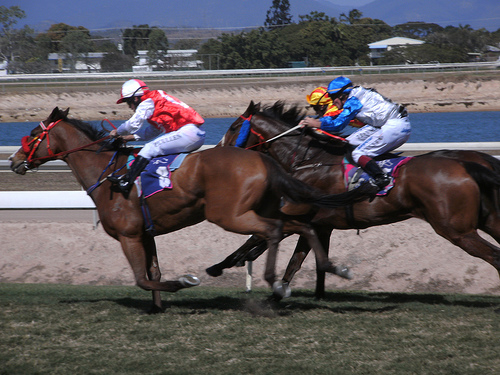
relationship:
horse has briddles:
[7, 103, 357, 320] [19, 112, 131, 173]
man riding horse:
[7, 71, 355, 318] [7, 103, 357, 320]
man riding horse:
[298, 76, 413, 192] [203, 97, 498, 294]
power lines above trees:
[11, 16, 498, 50] [13, 38, 497, 67]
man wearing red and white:
[7, 71, 355, 318] [108, 89, 208, 195]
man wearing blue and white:
[298, 76, 413, 192] [314, 72, 415, 196]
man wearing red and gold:
[205, 79, 500, 312] [308, 83, 367, 134]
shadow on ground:
[56, 290, 253, 326] [6, 281, 495, 361]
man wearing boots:
[7, 71, 355, 318] [107, 152, 158, 199]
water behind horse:
[0, 109, 498, 141] [7, 103, 357, 320]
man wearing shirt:
[7, 71, 355, 318] [110, 89, 212, 153]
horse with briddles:
[203, 97, 498, 294] [212, 105, 323, 155]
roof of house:
[137, 46, 198, 56] [131, 46, 205, 77]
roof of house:
[365, 33, 428, 49] [366, 34, 428, 68]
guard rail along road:
[1, 59, 499, 81] [4, 71, 494, 86]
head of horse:
[7, 102, 74, 178] [7, 103, 357, 320]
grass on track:
[1, 279, 485, 370] [6, 281, 495, 361]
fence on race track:
[1, 138, 495, 222] [6, 281, 495, 361]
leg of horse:
[204, 233, 259, 280] [203, 97, 498, 294]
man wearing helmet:
[300, 73, 416, 206] [326, 71, 360, 99]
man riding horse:
[300, 73, 416, 206] [203, 97, 498, 294]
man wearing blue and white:
[300, 73, 416, 206] [314, 72, 415, 196]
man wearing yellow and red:
[300, 73, 416, 206] [308, 83, 367, 134]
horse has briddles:
[203, 97, 498, 294] [212, 105, 323, 155]